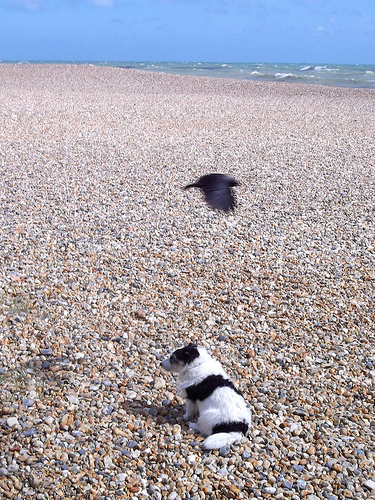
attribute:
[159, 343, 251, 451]
dog — small, black, white, sitting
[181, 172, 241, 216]
bird — black, flying, blurry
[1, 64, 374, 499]
rocks — colorful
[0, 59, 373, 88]
ocean — blue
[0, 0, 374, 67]
sky — blue, clear